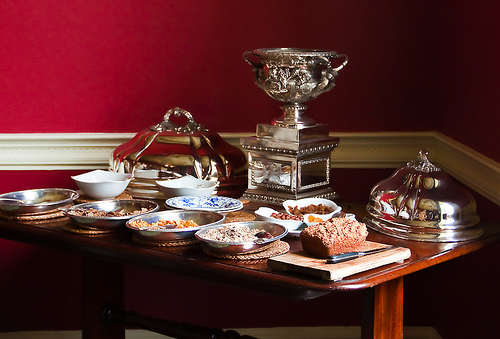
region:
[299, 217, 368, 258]
a brown loaf on a cutting board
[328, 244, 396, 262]
a knife on a cutting board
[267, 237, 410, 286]
a cutting board on a table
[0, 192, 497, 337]
a brown wooden table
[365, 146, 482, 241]
a silver lid on a table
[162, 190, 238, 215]
two blue and white bowls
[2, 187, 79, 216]
a silver bowl with a utensil inside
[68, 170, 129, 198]
a white bowl in front of a large silver lid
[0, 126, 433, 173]
a white chair rail on a wall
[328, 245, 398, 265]
A knife on the cutting board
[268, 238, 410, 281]
A cutting board on tthe table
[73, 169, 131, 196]
A white bowl on the table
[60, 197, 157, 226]
A silver bowl full of food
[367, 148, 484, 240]
The platter is silver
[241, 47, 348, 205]
A trophy on the table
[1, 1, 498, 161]
The wall behind the table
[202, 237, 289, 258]
A cozy under the bowls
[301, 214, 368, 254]
Bread on the cutting board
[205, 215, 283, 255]
this is a plate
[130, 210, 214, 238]
this is a plate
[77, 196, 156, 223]
this is a plate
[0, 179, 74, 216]
this is a plate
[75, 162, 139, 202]
this is a plate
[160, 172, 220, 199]
this is a plate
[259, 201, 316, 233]
this is a plate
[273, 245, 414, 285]
this is a chopping board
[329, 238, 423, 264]
this is a knife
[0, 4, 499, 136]
this is a red wall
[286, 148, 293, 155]
silver dot on base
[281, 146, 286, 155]
silver dot on base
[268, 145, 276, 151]
silver dot on base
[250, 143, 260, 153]
silver dot on base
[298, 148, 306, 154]
silver dot on base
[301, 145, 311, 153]
silver dot on base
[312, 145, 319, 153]
silver dot on base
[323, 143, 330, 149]
silver dot on base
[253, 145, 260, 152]
silver dot on base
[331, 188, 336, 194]
silver dot on base